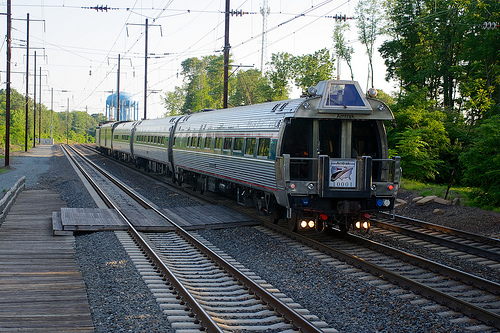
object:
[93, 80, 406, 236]
train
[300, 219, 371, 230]
lights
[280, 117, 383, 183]
door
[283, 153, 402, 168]
rails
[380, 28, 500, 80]
leaves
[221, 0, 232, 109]
pole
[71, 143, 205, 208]
stones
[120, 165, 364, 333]
middle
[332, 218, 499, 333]
tracks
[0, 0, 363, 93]
electric lines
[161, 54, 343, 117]
trees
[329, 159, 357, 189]
sign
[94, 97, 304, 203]
four cars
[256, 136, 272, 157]
window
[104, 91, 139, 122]
water tower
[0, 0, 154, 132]
distance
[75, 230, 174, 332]
rocks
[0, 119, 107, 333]
side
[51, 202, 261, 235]
board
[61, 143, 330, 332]
tracks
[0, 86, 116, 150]
row of trees